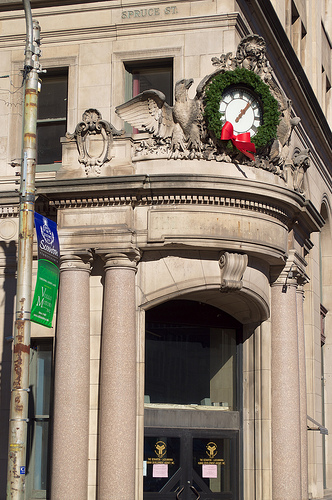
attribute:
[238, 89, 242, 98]
roman numeral — black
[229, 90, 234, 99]
roman numeral — black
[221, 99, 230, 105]
roman numeral — black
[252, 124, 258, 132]
roman numeral — black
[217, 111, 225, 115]
roman numeral — black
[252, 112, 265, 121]
number — black, Roman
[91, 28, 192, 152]
window — glass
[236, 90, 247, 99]
roman numeral — black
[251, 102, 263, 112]
numeral — black, roman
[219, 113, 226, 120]
numeral — black, roman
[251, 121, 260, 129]
numeral — roman, black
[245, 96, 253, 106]
roman numeral — black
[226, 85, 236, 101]
roman numeral — black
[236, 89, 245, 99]
roman numeral — black